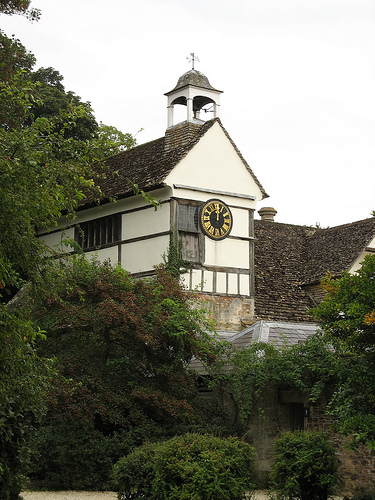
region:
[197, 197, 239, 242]
Black round clock face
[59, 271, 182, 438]
Green and red shrubs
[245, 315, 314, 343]
grey shingled roof top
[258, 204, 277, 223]
Chimney on top of roof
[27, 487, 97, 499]
Dead grass in the yard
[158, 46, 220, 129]
White and black bell tower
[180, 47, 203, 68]
Weathervane on top of bell tower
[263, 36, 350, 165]
White clear sky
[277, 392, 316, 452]
Doorway covered in ivy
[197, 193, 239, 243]
clock on a building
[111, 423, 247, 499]
green bush in front of a house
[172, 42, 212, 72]
weather vane on top of a building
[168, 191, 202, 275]
window of a building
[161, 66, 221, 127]
bell tower on top of building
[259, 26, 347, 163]
cloudy sky in the distance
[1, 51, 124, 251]
green leaves on a tree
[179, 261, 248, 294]
architecture on a building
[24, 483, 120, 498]
sidewalk by the trees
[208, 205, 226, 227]
hands of a clock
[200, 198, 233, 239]
a black and gold clock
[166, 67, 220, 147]
a bell tower on a building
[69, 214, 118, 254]
window with bars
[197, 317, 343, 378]
roof of a small house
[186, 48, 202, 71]
a metal directional tell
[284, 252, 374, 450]
the green leaves of a tree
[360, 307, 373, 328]
yellow leaves on a tree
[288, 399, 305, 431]
an entry way to a building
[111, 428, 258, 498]
a green bush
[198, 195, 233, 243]
a clock on the side of a building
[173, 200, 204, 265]
a window in a building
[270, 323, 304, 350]
the shingles of a roof of a building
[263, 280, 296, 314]
the shingles of a roof of a building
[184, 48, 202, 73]
a weather vane on top of a building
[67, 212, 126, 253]
the window of a building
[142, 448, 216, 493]
the leaves of a bush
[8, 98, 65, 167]
the leaves of a tree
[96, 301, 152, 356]
the leaves of a tree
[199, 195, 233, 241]
Black and gold analog clock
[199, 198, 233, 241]
Analog clock with roman numerals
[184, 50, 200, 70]
Weathervane on top of a building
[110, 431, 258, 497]
Large untrimmed bush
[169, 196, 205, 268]
Old window with wood frame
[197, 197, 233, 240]
Analog clock on a building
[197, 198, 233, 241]
Black analog clock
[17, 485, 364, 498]
Gravel driveway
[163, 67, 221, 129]
Bell on top of a building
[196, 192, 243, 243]
black and white clock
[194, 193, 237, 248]
black and white clock on building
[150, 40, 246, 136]
steeple on white building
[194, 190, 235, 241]
black and white clock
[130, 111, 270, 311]
white building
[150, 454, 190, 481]
green leaves on brown bush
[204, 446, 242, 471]
green leaves on brown bush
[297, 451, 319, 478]
green leaves on brown bush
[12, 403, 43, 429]
green leaves on brown bush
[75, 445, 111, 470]
green leaves on brown bush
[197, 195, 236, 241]
a round clock on a building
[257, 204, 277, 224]
a metal vent pipe on a roof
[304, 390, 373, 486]
a rock wall on a building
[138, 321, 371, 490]
a building surround by trees